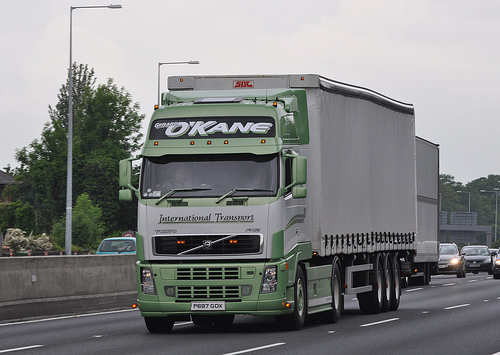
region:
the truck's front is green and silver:
[125, 87, 317, 314]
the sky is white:
[189, 25, 374, 64]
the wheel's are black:
[280, 238, 465, 335]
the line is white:
[361, 312, 408, 334]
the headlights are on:
[437, 253, 465, 268]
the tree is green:
[70, 80, 122, 183]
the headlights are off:
[119, 260, 288, 321]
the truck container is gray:
[287, 62, 430, 259]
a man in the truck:
[147, 137, 220, 205]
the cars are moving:
[441, 236, 498, 281]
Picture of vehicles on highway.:
[50, 12, 472, 348]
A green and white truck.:
[125, 68, 332, 340]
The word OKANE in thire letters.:
[161, 112, 276, 139]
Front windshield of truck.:
[128, 132, 290, 208]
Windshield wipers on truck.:
[124, 171, 281, 211]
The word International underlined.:
[146, 205, 217, 227]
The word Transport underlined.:
[213, 208, 260, 225]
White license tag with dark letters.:
[181, 297, 234, 312]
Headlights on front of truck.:
[121, 257, 290, 299]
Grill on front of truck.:
[166, 260, 246, 307]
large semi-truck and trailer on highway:
[136, 67, 419, 317]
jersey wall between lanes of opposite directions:
[1, 250, 136, 316]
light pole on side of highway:
[62, 1, 130, 254]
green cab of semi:
[128, 85, 339, 347]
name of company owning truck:
[152, 111, 274, 139]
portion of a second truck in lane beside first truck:
[412, 132, 443, 296]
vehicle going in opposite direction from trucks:
[93, 232, 140, 255]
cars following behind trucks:
[441, 238, 498, 285]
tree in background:
[24, 60, 146, 229]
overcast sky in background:
[138, 4, 495, 81]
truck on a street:
[110, 62, 449, 343]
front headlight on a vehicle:
[256, 261, 281, 301]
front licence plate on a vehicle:
[182, 296, 231, 318]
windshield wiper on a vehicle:
[210, 183, 277, 208]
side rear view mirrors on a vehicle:
[272, 139, 315, 206]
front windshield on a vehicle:
[129, 143, 287, 208]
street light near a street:
[46, 0, 138, 272]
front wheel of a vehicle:
[282, 255, 315, 337]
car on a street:
[454, 238, 498, 285]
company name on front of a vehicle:
[152, 208, 266, 228]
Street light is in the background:
[60, 1, 134, 259]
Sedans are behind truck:
[435, 206, 498, 321]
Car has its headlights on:
[438, 234, 478, 290]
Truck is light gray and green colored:
[121, 44, 463, 326]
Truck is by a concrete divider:
[4, 244, 153, 327]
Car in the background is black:
[455, 234, 497, 281]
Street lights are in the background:
[448, 179, 498, 225]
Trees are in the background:
[445, 160, 498, 223]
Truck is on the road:
[118, 58, 485, 353]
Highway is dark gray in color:
[44, 308, 498, 353]